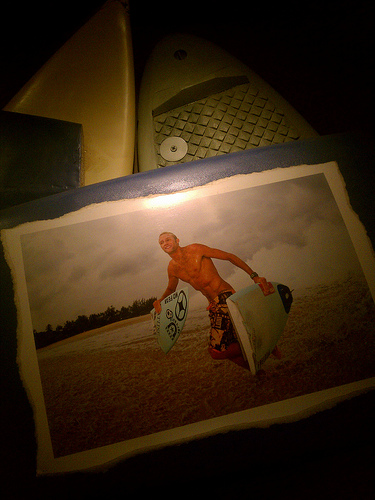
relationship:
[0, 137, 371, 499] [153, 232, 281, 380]
photo of man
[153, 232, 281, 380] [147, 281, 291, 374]
man with surfboard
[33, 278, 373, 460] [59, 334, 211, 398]
sand on beach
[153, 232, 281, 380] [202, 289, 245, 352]
man in trunks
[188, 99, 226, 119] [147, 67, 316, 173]
diamond on board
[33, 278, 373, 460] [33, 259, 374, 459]
sand on ground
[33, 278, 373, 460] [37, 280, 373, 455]
sand on ground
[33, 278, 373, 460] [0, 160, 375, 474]
sand in photo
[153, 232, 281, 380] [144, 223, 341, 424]
man on picture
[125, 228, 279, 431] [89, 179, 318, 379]
man on picture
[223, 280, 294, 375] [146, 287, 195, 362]
surf board in piece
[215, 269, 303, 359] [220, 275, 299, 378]
board in piece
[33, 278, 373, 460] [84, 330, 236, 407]
sand on ground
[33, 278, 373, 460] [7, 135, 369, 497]
sand in picture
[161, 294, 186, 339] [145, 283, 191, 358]
designs on surfboard